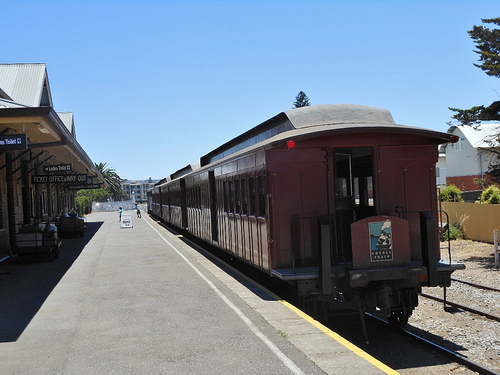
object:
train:
[148, 104, 466, 327]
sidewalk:
[0, 212, 401, 375]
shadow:
[0, 221, 105, 343]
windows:
[153, 176, 267, 218]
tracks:
[384, 292, 498, 358]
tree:
[465, 11, 499, 78]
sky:
[0, 25, 500, 180]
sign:
[121, 211, 134, 228]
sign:
[43, 163, 71, 173]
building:
[0, 62, 107, 262]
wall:
[0, 164, 32, 229]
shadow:
[157, 215, 283, 301]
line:
[273, 296, 402, 375]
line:
[145, 217, 305, 375]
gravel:
[423, 310, 468, 330]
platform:
[0, 202, 362, 370]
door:
[332, 146, 381, 265]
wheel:
[381, 290, 419, 326]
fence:
[439, 202, 500, 244]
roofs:
[0, 62, 54, 108]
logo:
[368, 221, 395, 263]